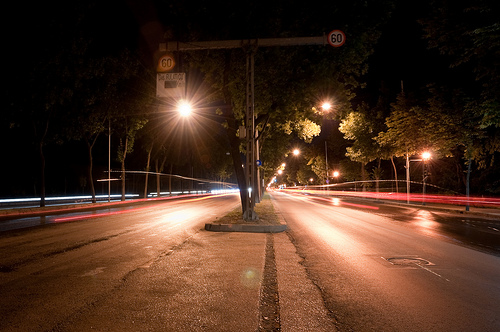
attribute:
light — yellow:
[318, 96, 334, 115]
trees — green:
[258, 44, 388, 182]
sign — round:
[317, 26, 350, 55]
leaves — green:
[338, 112, 373, 141]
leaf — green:
[309, 119, 313, 126]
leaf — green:
[283, 119, 297, 126]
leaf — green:
[298, 109, 299, 110]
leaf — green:
[296, 113, 304, 120]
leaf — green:
[305, 131, 309, 135]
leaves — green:
[404, 108, 436, 128]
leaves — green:
[216, 67, 257, 114]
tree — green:
[420, 77, 498, 204]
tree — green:
[367, 76, 468, 199]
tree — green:
[330, 88, 390, 195]